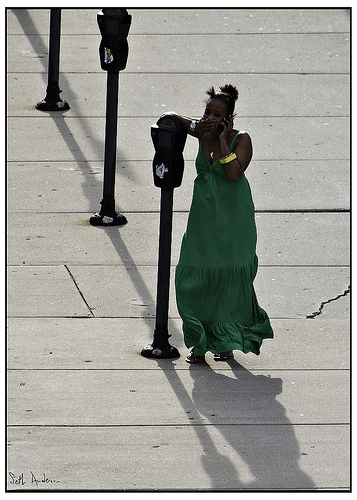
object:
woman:
[172, 81, 275, 366]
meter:
[93, 6, 133, 231]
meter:
[146, 116, 188, 363]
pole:
[36, 6, 72, 113]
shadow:
[180, 355, 313, 492]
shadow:
[112, 231, 145, 306]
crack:
[305, 281, 349, 328]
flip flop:
[184, 347, 203, 362]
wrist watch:
[192, 119, 198, 135]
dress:
[173, 131, 272, 357]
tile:
[250, 264, 352, 319]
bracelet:
[214, 150, 240, 166]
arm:
[171, 114, 201, 133]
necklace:
[208, 150, 216, 162]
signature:
[10, 472, 63, 488]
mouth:
[206, 120, 219, 130]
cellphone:
[218, 110, 235, 131]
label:
[102, 48, 112, 64]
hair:
[206, 83, 242, 110]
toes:
[188, 356, 196, 361]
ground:
[6, 14, 352, 494]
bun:
[219, 82, 241, 94]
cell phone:
[216, 117, 232, 133]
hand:
[219, 114, 236, 135]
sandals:
[190, 350, 237, 365]